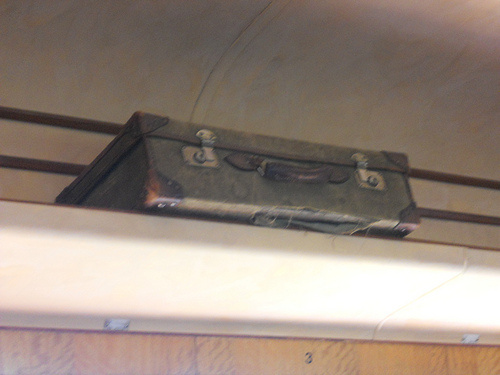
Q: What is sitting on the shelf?
A: Suitcase.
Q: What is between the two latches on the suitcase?
A: Handle.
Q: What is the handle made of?
A: Leather.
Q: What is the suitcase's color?
A: Green and brown.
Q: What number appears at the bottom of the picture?
A: 3.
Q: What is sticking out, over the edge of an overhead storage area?
A: A piece of luggage.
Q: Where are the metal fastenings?
A: On the front of the piece of luggage.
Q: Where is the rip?
A: On the bottom of the suitcase..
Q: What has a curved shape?
A: The ceiling above the suitcase.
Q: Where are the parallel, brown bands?
A: The bands are running across the wall.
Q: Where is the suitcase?
A: On the cream-colored ledge of a storage area.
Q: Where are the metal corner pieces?
A: On the suitcase.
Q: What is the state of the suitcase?
A: The suitcase is old and very used.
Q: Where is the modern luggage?
A: There is none visible.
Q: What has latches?
A: The suitcase.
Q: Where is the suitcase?
A: On a luggage rack.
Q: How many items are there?
A: One.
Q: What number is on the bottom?
A: Three.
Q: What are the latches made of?
A: Metal.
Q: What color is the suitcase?
A: Green.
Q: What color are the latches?
A: Silver.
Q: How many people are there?
A: Zero.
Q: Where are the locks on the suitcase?
A: Each side of handle.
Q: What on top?
A: A box.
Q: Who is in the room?
A: No one.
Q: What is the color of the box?
A: Grey.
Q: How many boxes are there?
A: 1.